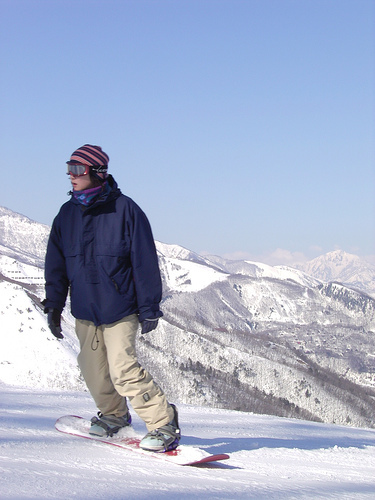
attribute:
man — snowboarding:
[36, 139, 188, 449]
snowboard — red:
[61, 412, 232, 465]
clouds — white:
[188, 197, 337, 239]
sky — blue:
[171, 12, 368, 238]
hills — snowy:
[8, 205, 281, 385]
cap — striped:
[68, 141, 113, 169]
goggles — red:
[65, 161, 99, 178]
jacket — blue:
[45, 174, 165, 321]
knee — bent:
[101, 358, 164, 406]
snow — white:
[65, 456, 329, 496]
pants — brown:
[66, 315, 184, 431]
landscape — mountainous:
[12, 203, 372, 391]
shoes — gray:
[93, 414, 188, 443]